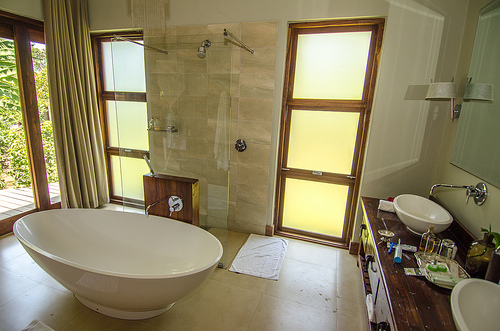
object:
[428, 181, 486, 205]
faucet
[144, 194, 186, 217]
faucet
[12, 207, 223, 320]
bathtub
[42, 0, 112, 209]
curtain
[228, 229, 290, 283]
towel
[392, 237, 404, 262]
toothbrush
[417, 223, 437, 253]
bottle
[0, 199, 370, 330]
floor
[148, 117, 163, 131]
soap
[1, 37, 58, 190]
leaves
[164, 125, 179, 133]
soap holder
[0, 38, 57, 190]
bush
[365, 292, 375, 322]
rag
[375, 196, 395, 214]
rag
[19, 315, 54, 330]
towel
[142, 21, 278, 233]
stone wall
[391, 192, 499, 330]
sinks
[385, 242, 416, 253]
toothpaste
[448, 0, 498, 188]
mirror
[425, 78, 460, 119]
lamp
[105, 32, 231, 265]
glass walls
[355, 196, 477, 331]
vanity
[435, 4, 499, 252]
wall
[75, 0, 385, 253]
wall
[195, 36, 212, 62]
shower head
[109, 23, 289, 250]
enclosure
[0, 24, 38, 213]
window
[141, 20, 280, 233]
wall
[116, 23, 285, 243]
shower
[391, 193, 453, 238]
sink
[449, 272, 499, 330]
sink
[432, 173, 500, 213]
counter top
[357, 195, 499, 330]
counter